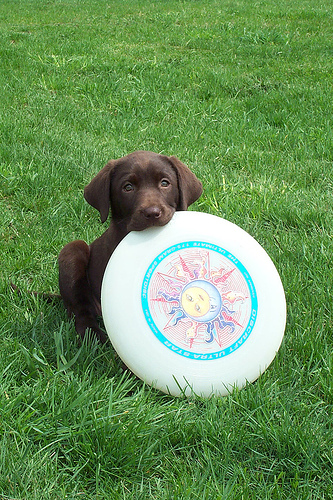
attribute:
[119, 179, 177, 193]
eyes — brown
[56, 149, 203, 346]
puppy — brown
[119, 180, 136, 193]
eye — brown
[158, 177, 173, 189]
eye — brown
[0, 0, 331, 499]
grass — long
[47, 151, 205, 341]
puppy — young, brown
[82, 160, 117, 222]
ear — brown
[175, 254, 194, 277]
ray — red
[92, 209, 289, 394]
frisbee — white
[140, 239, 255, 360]
circle — blue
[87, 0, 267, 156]
grass — green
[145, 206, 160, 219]
nose — brown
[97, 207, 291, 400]
white frisbee — round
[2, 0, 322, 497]
field — green